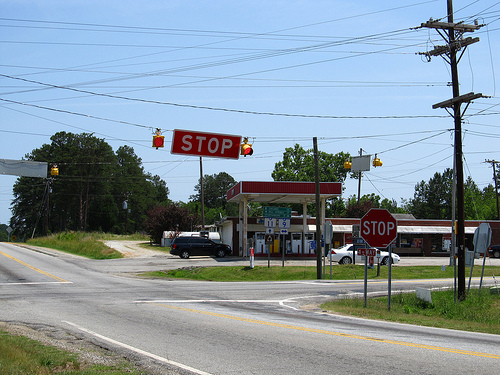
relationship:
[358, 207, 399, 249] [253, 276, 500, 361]
sign at intersection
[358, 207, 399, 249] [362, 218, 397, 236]
sign says stop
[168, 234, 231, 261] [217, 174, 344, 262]
suv at gas station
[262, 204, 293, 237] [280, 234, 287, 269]
signs on pole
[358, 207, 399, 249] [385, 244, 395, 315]
sign on pole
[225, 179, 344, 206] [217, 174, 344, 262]
awning over gas station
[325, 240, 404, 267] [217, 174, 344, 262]
car by gas station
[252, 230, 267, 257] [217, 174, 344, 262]
pump at gas station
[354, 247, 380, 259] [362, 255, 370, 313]
4 way sign on pole